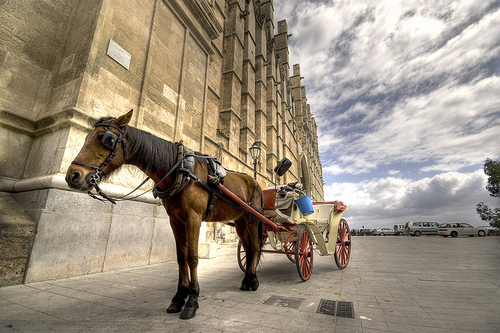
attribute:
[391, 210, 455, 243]
car — parked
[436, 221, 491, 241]
car — parked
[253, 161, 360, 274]
carriage — parked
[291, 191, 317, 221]
bucket — blue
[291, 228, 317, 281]
wheel — red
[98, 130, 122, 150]
block — black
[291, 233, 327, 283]
wheels — red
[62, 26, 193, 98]
plaque — white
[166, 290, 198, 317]
hooves — black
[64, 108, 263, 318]
horse — brown, parked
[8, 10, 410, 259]
building — huge